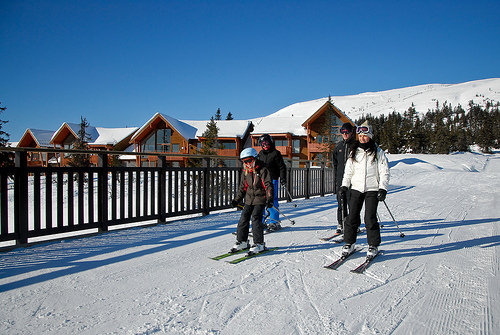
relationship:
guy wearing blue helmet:
[229, 145, 275, 255] [239, 145, 256, 160]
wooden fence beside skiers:
[0, 146, 335, 252] [229, 123, 394, 255]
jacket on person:
[258, 150, 283, 169] [252, 125, 288, 232]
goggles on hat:
[356, 126, 372, 136] [355, 116, 376, 139]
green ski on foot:
[211, 245, 249, 260] [246, 242, 265, 254]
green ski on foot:
[226, 248, 272, 264] [229, 241, 251, 252]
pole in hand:
[378, 192, 407, 238] [377, 187, 387, 202]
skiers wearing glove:
[340, 121, 395, 256] [376, 188, 386, 199]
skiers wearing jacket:
[340, 121, 395, 256] [333, 143, 392, 193]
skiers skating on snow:
[340, 121, 395, 256] [1, 144, 499, 334]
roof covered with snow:
[212, 75, 414, 266] [282, 118, 306, 130]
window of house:
[216, 139, 236, 151] [252, 99, 352, 166]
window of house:
[216, 139, 236, 151] [132, 109, 251, 165]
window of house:
[216, 139, 236, 151] [51, 120, 136, 169]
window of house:
[216, 139, 236, 151] [15, 122, 55, 169]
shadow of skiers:
[343, 234, 499, 264] [340, 121, 395, 256]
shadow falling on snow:
[343, 234, 499, 264] [1, 75, 498, 331]